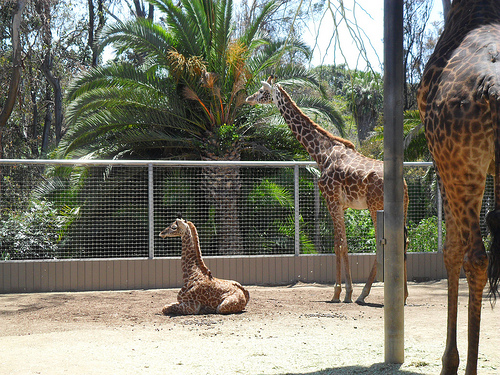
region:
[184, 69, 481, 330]
Three giraffe in the zoo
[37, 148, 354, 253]
A fence to secured the giraffe in.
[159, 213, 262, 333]
The giraffe is sitting on the ground.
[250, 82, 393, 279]
The giraffe is standing by the fence.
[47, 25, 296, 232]
Trees behind the fence.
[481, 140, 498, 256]
The giraffe has a long black tail.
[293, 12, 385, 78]
Branches hanging from the tree.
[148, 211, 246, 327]
The giraffe is brown and white.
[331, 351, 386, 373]
Shadow on the ground.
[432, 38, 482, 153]
The giraffe has brown spots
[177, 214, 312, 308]
This is a baby giraffe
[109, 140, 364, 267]
This is a fence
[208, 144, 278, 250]
The fence is metal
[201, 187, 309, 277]
The fence is silver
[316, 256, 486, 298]
This is a pole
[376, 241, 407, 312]
The pole is metal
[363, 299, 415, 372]
The pole is silver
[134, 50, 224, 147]
This is a palm tree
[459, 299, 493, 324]
This is a foot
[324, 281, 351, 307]
This is a hoof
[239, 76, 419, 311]
tall giraffe looking at trees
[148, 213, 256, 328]
small giraffe is sitting on ground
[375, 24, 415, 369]
small pole beside giraffe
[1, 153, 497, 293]
tall fence separating animals and trees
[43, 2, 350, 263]
large palm tree behind fence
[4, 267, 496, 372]
ground is mostly dirt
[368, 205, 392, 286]
box attached to pole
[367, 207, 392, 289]
box on pole is metal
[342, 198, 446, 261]
small green vines behind fence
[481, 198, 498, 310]
black tail hanging behind giraffe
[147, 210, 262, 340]
the giraffe in the area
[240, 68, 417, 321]
the giraffe is standing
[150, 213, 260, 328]
the giraffe is laying down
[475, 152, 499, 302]
the tail of the giraffe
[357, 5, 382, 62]
the sky is blue and clear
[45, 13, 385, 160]
the palm tree beside the fence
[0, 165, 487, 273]
the fence is silver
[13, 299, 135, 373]
the sand in the area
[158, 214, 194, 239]
the head of the giraffe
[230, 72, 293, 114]
the head of the giraffe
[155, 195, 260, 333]
small brown and beige giraffe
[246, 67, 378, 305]
tall brown and beige griraffe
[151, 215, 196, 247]
face of a giraffe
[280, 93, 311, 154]
long neck of a giraffe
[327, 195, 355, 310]
legs of a giraffe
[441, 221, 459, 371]
leg of a giraffe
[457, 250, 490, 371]
leg of a griaffe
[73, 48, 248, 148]
palm tree near a giraffe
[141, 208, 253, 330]
small giraffe sitting near fence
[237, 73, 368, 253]
giraffe standing near a fence